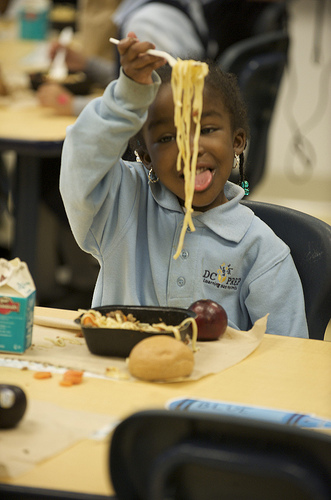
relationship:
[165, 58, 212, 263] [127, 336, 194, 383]
noodles for bread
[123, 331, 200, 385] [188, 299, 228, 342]
bread near apple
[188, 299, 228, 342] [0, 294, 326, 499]
apple on table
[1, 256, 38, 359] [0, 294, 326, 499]
milk carton on table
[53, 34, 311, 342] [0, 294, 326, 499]
girl at table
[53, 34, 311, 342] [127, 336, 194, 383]
girl eating bread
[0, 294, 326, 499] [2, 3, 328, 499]
table in cafeteria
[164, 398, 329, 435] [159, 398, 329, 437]
crayon on sign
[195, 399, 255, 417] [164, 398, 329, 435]
word on crayon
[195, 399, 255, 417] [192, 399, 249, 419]
word says blue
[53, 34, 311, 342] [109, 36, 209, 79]
girl holds fork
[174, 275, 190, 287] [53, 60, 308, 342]
button on shirt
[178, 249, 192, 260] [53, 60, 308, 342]
button on shirt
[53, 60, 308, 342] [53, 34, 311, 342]
shirt on girl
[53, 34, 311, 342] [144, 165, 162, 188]
girl wears earring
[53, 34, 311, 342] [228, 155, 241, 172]
girl wears earring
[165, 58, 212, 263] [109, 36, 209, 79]
noodles in spoon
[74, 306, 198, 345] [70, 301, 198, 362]
noodles in container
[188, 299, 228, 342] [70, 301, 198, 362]
apple next to container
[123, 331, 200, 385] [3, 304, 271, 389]
bread roll on paper towel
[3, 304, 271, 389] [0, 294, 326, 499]
paper towel on table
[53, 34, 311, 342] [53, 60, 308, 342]
girl wears shirt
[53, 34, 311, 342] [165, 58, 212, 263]
girl holds noodles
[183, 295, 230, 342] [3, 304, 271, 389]
apple on paper towel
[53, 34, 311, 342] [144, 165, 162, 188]
girl has earring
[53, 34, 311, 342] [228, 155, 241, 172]
girl has earring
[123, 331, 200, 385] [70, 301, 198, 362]
bread roll by container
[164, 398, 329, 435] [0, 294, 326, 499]
crayon on table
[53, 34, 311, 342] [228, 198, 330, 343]
girl on chair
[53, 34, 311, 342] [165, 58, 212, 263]
girl picks up noodles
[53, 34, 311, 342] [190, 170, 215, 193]
girl has tongue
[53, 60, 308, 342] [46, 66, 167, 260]
shirt has sleeve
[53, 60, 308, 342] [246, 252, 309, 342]
shirt has sleeve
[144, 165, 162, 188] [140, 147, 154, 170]
earring on ear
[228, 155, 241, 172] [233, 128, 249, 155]
earring on ear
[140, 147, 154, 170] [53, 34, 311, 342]
ear on girl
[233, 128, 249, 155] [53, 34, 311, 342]
ear on girl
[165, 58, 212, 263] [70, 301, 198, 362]
noodles in container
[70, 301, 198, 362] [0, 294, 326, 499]
container on table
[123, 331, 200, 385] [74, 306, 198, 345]
bread next to noodles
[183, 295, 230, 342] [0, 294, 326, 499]
apple on table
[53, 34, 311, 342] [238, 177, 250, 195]
girl has beads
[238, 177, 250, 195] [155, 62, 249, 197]
beads in hair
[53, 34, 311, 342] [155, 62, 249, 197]
girl has hair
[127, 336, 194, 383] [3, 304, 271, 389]
bread on paper towel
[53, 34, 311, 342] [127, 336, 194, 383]
girl eats bread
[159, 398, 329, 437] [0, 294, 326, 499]
picture on table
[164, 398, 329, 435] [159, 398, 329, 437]
crayon on picture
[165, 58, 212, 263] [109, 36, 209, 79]
noodles on fork